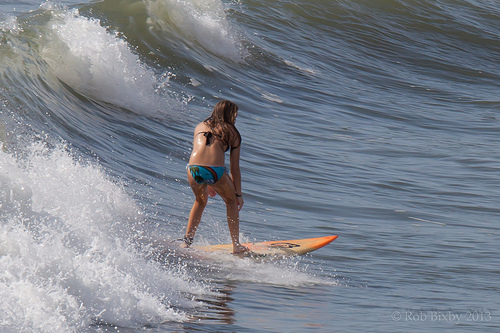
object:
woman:
[183, 100, 250, 253]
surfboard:
[180, 235, 338, 256]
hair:
[203, 100, 241, 152]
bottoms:
[186, 165, 230, 185]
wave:
[0, 0, 337, 332]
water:
[0, 0, 498, 332]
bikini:
[185, 131, 229, 184]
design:
[268, 242, 300, 248]